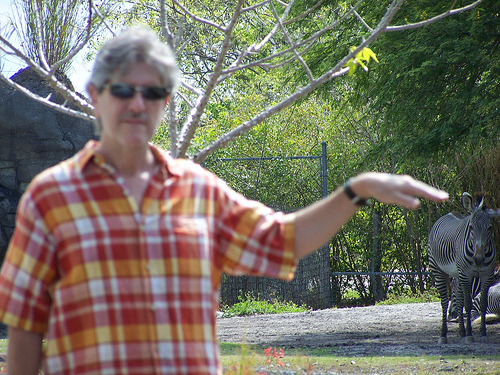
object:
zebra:
[427, 192, 500, 344]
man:
[0, 30, 452, 374]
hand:
[353, 171, 448, 209]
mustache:
[119, 112, 149, 120]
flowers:
[262, 345, 283, 369]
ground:
[0, 291, 498, 370]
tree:
[362, 198, 394, 304]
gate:
[332, 271, 432, 309]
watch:
[343, 182, 367, 206]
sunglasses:
[105, 83, 173, 102]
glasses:
[105, 78, 175, 103]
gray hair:
[86, 25, 179, 92]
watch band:
[343, 180, 367, 206]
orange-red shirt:
[1, 140, 298, 374]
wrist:
[348, 172, 375, 203]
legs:
[432, 270, 449, 334]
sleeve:
[1, 190, 57, 333]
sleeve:
[215, 171, 294, 281]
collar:
[76, 138, 184, 178]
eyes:
[469, 225, 473, 229]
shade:
[392, 148, 499, 357]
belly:
[437, 257, 458, 273]